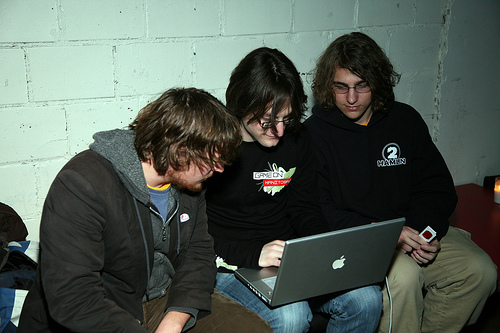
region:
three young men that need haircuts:
[36, 26, 499, 331]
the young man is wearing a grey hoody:
[36, 123, 218, 331]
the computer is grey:
[235, 213, 412, 307]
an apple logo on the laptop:
[331, 252, 350, 271]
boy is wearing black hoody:
[301, 95, 465, 254]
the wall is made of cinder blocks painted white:
[3, 0, 498, 254]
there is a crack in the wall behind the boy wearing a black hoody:
[426, 1, 457, 159]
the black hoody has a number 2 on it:
[385, 145, 399, 162]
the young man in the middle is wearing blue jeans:
[210, 262, 389, 332]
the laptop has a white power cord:
[382, 271, 399, 331]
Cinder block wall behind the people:
[1, 1, 448, 236]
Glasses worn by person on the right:
[330, 81, 373, 96]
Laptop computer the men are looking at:
[228, 212, 404, 308]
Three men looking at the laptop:
[15, 27, 495, 327]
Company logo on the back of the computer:
[330, 253, 349, 272]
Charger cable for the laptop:
[382, 276, 394, 331]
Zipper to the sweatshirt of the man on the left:
[161, 223, 169, 243]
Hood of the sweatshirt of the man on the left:
[85, 123, 152, 204]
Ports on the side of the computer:
[242, 279, 269, 305]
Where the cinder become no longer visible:
[432, 0, 454, 157]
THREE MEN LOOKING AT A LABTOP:
[34, 33, 494, 331]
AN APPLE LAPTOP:
[230, 215, 437, 312]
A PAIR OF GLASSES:
[328, 73, 380, 96]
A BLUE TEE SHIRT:
[144, 181, 186, 224]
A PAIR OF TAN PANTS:
[374, 216, 496, 329]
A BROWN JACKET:
[38, 146, 229, 329]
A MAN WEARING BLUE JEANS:
[213, 43, 393, 328]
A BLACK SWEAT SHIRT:
[296, 101, 462, 235]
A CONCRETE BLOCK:
[13, 33, 130, 105]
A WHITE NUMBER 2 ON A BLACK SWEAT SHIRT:
[378, 143, 416, 170]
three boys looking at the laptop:
[77, 33, 437, 330]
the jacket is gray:
[67, 153, 212, 289]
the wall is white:
[20, 20, 122, 89]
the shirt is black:
[232, 155, 329, 232]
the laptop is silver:
[244, 233, 427, 331]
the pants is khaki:
[380, 224, 467, 326]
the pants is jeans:
[225, 263, 380, 332]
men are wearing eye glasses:
[264, 73, 383, 144]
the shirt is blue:
[146, 184, 167, 205]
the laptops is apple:
[291, 247, 381, 291]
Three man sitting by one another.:
[71, 35, 498, 307]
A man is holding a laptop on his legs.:
[235, 87, 382, 313]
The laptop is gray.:
[251, 233, 411, 302]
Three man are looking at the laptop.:
[53, 28, 463, 310]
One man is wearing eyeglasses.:
[253, 110, 300, 143]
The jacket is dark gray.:
[51, 162, 223, 321]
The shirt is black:
[230, 145, 326, 248]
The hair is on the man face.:
[246, 68, 306, 137]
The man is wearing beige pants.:
[393, 221, 493, 325]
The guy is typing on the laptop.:
[239, 85, 378, 306]